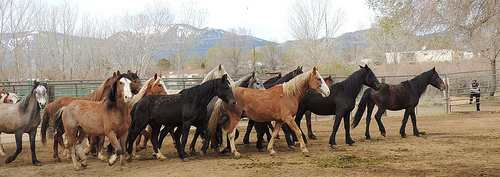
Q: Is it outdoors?
A: Yes, it is outdoors.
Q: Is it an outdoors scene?
A: Yes, it is outdoors.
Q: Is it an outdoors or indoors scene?
A: It is outdoors.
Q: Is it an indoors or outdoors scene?
A: It is outdoors.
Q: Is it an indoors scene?
A: No, it is outdoors.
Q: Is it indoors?
A: No, it is outdoors.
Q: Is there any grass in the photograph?
A: Yes, there is grass.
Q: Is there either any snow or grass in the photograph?
A: Yes, there is grass.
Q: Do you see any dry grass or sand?
A: Yes, there is dry grass.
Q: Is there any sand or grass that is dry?
A: Yes, the grass is dry.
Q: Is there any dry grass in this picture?
A: Yes, there is dry grass.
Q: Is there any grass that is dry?
A: Yes, there is grass that is dry.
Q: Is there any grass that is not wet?
A: Yes, there is dry grass.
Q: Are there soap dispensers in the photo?
A: No, there are no soap dispensers.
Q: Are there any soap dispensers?
A: No, there are no soap dispensers.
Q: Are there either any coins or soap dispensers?
A: No, there are no soap dispensers or coins.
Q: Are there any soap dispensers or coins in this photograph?
A: No, there are no soap dispensers or coins.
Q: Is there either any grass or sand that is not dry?
A: No, there is grass but it is dry.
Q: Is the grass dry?
A: Yes, the grass is dry.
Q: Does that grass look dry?
A: Yes, the grass is dry.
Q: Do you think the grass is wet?
A: No, the grass is dry.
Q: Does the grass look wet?
A: No, the grass is dry.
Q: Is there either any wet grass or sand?
A: No, there is grass but it is dry.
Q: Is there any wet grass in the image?
A: No, there is grass but it is dry.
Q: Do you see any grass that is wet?
A: No, there is grass but it is dry.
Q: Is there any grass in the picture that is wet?
A: No, there is grass but it is dry.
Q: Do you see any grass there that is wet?
A: No, there is grass but it is dry.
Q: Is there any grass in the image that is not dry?
A: No, there is grass but it is dry.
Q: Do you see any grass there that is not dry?
A: No, there is grass but it is dry.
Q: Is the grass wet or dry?
A: The grass is dry.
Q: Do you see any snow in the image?
A: Yes, there is snow.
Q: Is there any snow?
A: Yes, there is snow.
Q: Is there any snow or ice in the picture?
A: Yes, there is snow.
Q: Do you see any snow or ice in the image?
A: Yes, there is snow.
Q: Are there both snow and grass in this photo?
A: Yes, there are both snow and grass.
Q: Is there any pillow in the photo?
A: No, there are no pillows.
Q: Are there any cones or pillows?
A: No, there are no pillows or cones.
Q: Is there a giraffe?
A: No, there are no giraffes.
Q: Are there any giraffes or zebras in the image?
A: No, there are no giraffes or zebras.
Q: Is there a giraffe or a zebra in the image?
A: No, there are no giraffes or zebras.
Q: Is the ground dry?
A: Yes, the ground is dry.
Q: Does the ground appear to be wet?
A: No, the ground is dry.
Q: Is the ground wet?
A: No, the ground is dry.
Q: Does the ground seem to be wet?
A: No, the ground is dry.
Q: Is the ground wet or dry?
A: The ground is dry.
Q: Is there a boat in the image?
A: No, there are no boats.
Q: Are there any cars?
A: No, there are no cars.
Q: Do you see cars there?
A: No, there are no cars.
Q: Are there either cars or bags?
A: No, there are no cars or bags.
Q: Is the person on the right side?
A: Yes, the person is on the right of the image.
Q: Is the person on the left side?
A: No, the person is on the right of the image.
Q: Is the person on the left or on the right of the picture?
A: The person is on the right of the image.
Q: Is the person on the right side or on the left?
A: The person is on the right of the image.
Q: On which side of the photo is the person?
A: The person is on the right of the image.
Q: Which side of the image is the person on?
A: The person is on the right of the image.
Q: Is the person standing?
A: Yes, the person is standing.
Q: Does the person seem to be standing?
A: Yes, the person is standing.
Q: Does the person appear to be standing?
A: Yes, the person is standing.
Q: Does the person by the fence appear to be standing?
A: Yes, the person is standing.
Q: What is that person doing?
A: The person is standing.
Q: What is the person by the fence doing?
A: The person is standing.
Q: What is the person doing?
A: The person is standing.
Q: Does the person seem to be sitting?
A: No, the person is standing.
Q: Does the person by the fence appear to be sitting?
A: No, the person is standing.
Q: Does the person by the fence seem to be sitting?
A: No, the person is standing.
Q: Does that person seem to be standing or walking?
A: The person is standing.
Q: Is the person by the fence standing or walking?
A: The person is standing.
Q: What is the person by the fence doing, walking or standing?
A: The person is standing.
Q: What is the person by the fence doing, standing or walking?
A: The person is standing.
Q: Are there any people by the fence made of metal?
A: Yes, there is a person by the fence.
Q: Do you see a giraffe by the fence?
A: No, there is a person by the fence.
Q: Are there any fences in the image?
A: Yes, there is a fence.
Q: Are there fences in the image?
A: Yes, there is a fence.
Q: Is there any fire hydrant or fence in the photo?
A: Yes, there is a fence.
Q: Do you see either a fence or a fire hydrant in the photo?
A: Yes, there is a fence.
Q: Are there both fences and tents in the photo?
A: No, there is a fence but no tents.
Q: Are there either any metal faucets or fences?
A: Yes, there is a metal fence.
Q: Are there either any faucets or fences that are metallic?
A: Yes, the fence is metallic.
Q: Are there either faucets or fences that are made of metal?
A: Yes, the fence is made of metal.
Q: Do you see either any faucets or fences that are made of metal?
A: Yes, the fence is made of metal.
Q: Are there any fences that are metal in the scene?
A: Yes, there is a metal fence.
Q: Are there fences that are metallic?
A: Yes, there is a fence that is metallic.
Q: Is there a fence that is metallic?
A: Yes, there is a fence that is metallic.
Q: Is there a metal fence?
A: Yes, there is a fence that is made of metal.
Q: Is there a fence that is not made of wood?
A: Yes, there is a fence that is made of metal.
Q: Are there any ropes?
A: No, there are no ropes.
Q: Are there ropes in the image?
A: No, there are no ropes.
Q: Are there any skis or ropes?
A: No, there are no ropes or skis.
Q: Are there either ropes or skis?
A: No, there are no ropes or skis.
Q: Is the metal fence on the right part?
A: Yes, the fence is on the right of the image.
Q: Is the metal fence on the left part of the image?
A: No, the fence is on the right of the image.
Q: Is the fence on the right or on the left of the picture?
A: The fence is on the right of the image.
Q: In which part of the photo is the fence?
A: The fence is on the right of the image.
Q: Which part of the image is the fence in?
A: The fence is on the right of the image.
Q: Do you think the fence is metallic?
A: Yes, the fence is metallic.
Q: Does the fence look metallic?
A: Yes, the fence is metallic.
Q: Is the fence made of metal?
A: Yes, the fence is made of metal.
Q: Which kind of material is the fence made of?
A: The fence is made of metal.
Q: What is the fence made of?
A: The fence is made of metal.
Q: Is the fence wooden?
A: No, the fence is metallic.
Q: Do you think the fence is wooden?
A: No, the fence is metallic.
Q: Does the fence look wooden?
A: No, the fence is metallic.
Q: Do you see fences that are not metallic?
A: No, there is a fence but it is metallic.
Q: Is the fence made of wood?
A: No, the fence is made of metal.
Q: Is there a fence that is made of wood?
A: No, there is a fence but it is made of metal.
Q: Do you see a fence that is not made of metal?
A: No, there is a fence but it is made of metal.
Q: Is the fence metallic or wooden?
A: The fence is metallic.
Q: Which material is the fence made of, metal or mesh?
A: The fence is made of metal.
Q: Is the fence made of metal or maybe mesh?
A: The fence is made of metal.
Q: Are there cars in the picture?
A: No, there are no cars.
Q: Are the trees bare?
A: Yes, the trees are bare.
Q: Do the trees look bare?
A: Yes, the trees are bare.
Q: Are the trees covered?
A: No, the trees are bare.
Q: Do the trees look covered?
A: No, the trees are bare.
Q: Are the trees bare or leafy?
A: The trees are bare.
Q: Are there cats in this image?
A: No, there are no cats.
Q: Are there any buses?
A: No, there are no buses.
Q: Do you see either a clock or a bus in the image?
A: No, there are no buses or clocks.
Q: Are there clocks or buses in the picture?
A: No, there are no buses or clocks.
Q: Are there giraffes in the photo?
A: No, there are no giraffes.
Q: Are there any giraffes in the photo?
A: No, there are no giraffes.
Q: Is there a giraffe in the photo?
A: No, there are no giraffes.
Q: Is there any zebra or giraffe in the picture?
A: No, there are no giraffes or zebras.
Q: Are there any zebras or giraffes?
A: No, there are no giraffes or zebras.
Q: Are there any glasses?
A: No, there are no glasses.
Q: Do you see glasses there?
A: No, there are no glasses.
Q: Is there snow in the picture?
A: Yes, there is snow.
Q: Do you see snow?
A: Yes, there is snow.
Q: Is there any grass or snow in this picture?
A: Yes, there is snow.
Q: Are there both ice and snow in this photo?
A: No, there is snow but no ice.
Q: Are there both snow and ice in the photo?
A: No, there is snow but no ice.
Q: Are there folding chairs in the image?
A: No, there are no folding chairs.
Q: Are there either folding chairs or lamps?
A: No, there are no folding chairs or lamps.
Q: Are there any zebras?
A: No, there are no zebras.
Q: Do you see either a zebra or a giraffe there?
A: No, there are no zebras or giraffes.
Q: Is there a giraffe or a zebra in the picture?
A: No, there are no zebras or giraffes.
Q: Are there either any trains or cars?
A: No, there are no cars or trains.